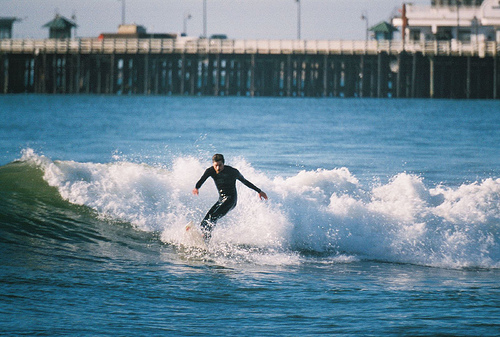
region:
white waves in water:
[343, 190, 462, 246]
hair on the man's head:
[211, 153, 224, 163]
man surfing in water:
[179, 150, 280, 263]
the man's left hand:
[252, 186, 267, 202]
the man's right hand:
[186, 188, 204, 195]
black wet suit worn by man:
[192, 169, 259, 245]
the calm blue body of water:
[287, 104, 448, 150]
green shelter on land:
[42, 12, 76, 36]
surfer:
[178, 135, 248, 230]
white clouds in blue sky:
[378, 3, 426, 34]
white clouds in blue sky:
[232, 9, 269, 27]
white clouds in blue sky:
[141, 8, 161, 25]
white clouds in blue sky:
[78, 11, 115, 43]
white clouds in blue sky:
[202, 18, 247, 38]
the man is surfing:
[117, 70, 313, 287]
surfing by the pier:
[43, 4, 423, 306]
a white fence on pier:
[28, 10, 430, 132]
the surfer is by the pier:
[54, 12, 429, 312]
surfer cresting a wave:
[156, 130, 313, 269]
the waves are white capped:
[111, 127, 333, 249]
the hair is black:
[174, 128, 291, 290]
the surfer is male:
[154, 125, 309, 321]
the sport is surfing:
[153, 117, 333, 284]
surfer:
[198, 145, 252, 257]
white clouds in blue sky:
[97, 18, 122, 30]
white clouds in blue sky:
[317, 16, 341, 37]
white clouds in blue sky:
[372, 0, 414, 31]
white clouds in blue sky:
[95, 8, 117, 25]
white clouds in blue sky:
[285, 11, 310, 41]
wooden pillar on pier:
[463, 63, 478, 108]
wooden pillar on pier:
[442, 62, 463, 103]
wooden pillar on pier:
[372, 61, 397, 106]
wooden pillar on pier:
[347, 59, 362, 97]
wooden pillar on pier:
[276, 65, 291, 89]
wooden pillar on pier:
[196, 55, 211, 100]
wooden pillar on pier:
[173, 63, 191, 98]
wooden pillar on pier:
[133, 58, 145, 88]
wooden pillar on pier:
[80, 65, 104, 102]